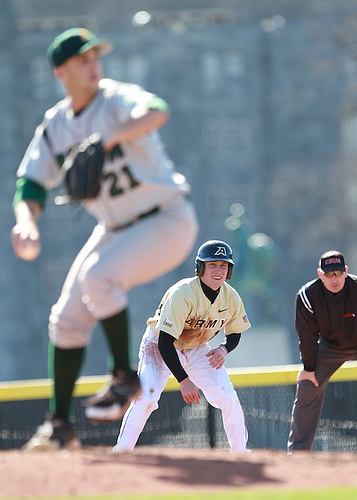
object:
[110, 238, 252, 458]
runner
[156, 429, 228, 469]
base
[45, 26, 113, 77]
helmet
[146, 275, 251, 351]
shirt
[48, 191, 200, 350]
pants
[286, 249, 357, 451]
umpire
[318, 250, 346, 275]
hat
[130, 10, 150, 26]
ball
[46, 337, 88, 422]
socks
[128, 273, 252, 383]
uniform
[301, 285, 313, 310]
stripes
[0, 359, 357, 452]
fence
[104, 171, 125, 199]
number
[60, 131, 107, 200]
glove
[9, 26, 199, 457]
man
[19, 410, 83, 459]
shoe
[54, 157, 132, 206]
mit